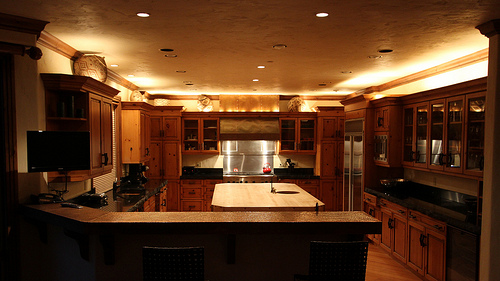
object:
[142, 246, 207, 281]
chair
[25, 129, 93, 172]
tv monitor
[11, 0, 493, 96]
ceiling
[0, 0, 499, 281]
room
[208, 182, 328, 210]
table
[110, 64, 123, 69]
light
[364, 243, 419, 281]
floor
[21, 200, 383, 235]
counter